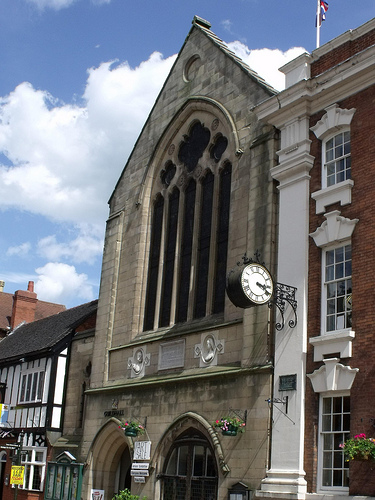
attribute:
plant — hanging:
[214, 415, 247, 435]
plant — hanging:
[117, 413, 144, 437]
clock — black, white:
[226, 247, 301, 330]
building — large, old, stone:
[76, 13, 272, 497]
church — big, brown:
[97, 40, 271, 495]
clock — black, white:
[225, 248, 275, 308]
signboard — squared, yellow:
[9, 465, 22, 483]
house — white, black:
[7, 296, 92, 485]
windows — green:
[39, 447, 89, 497]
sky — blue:
[0, 1, 372, 314]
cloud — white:
[22, 260, 95, 307]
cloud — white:
[0, 38, 305, 237]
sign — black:
[259, 370, 312, 393]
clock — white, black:
[223, 261, 291, 302]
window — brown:
[126, 90, 247, 347]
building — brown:
[38, 16, 280, 498]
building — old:
[251, 16, 370, 498]